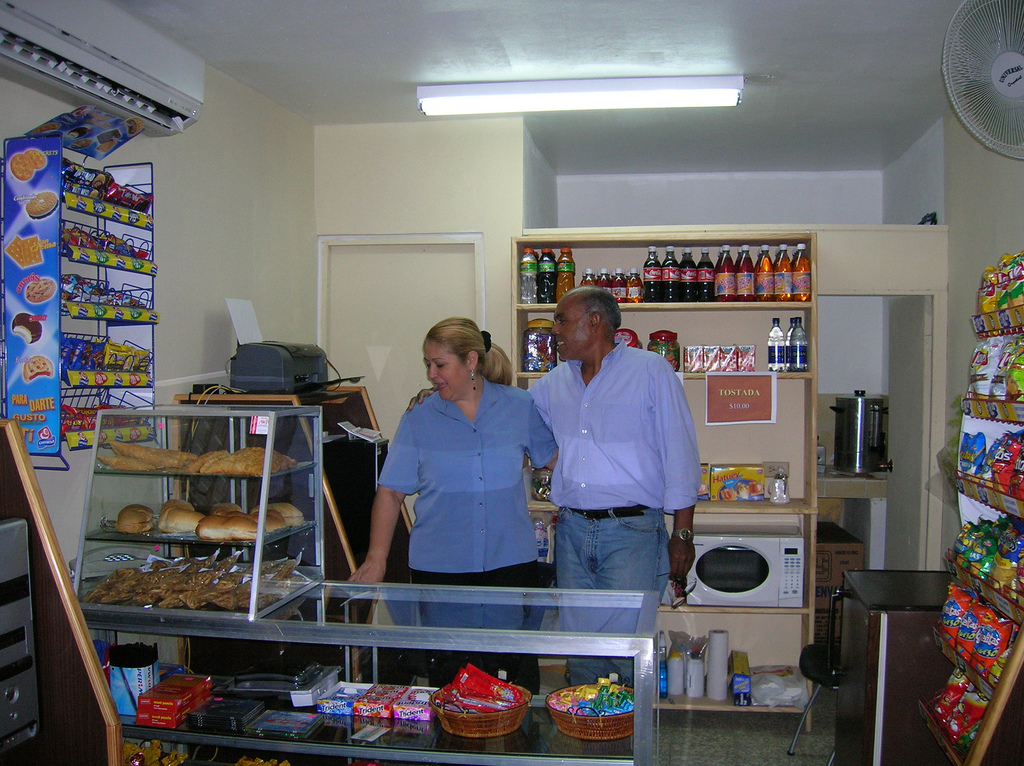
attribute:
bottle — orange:
[726, 285, 787, 348]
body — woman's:
[417, 437, 519, 494]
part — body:
[447, 532, 448, 550]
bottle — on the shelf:
[637, 277, 819, 306]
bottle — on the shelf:
[656, 277, 974, 286]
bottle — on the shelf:
[660, 264, 827, 306]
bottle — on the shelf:
[676, 262, 765, 288]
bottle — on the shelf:
[673, 264, 792, 284]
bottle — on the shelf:
[689, 275, 750, 278]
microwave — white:
[670, 512, 831, 636]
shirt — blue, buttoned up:
[326, 359, 595, 595]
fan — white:
[918, 13, 992, 201]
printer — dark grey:
[208, 305, 345, 429]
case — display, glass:
[69, 357, 359, 705]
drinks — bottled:
[512, 232, 841, 330]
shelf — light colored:
[519, 288, 826, 325]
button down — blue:
[517, 335, 712, 524]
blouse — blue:
[372, 376, 574, 573]